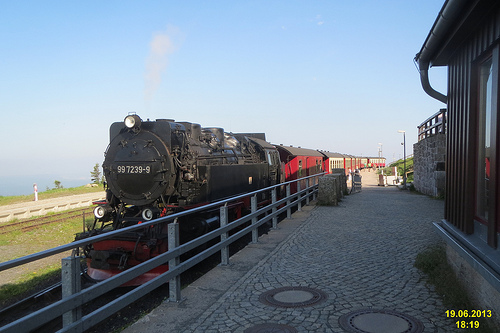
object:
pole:
[33, 184, 38, 202]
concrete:
[244, 209, 456, 331]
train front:
[91, 112, 176, 227]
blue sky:
[1, 2, 447, 195]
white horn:
[124, 116, 136, 129]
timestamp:
[445, 310, 493, 330]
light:
[123, 115, 136, 129]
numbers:
[117, 165, 151, 174]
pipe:
[416, 49, 451, 105]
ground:
[271, 180, 459, 333]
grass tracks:
[0, 197, 106, 237]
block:
[315, 173, 346, 206]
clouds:
[0, 0, 446, 134]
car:
[82, 113, 388, 290]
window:
[479, 62, 498, 154]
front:
[448, 16, 498, 250]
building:
[408, 0, 498, 325]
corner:
[444, 300, 500, 332]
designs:
[258, 284, 327, 308]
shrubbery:
[412, 243, 489, 332]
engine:
[70, 200, 189, 287]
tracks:
[0, 269, 154, 333]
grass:
[1, 204, 95, 297]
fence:
[0, 171, 332, 332]